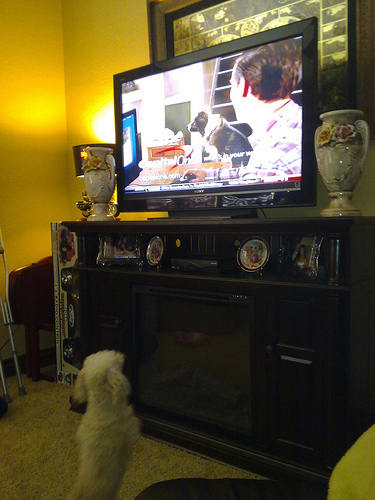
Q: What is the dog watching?
A: Television.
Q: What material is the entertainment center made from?
A: Wood.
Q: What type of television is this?
A: Flat screen.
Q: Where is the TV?
A: Entertainment center.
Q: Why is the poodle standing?
A: Watching TV.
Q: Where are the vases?
A: On the mantle.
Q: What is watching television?
A: A dog.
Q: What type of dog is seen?
A: A poodle.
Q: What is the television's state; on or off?
A: On.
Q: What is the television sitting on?
A: Entertainment center.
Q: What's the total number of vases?
A: 2.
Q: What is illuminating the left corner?
A: A lamp.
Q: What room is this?
A: Living room.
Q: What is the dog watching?
A: TV.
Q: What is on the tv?
A: Commercial.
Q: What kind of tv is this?
A: Flat screen.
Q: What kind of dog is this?
A: Poodle.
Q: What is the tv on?
A: Wooden stand.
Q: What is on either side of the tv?
A: Vases.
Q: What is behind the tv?
A: Picture.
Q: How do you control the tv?
A: Remote control.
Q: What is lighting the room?
A: Lamp.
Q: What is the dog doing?
A: Watching tv.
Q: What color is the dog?
A: White.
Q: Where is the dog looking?
A: At the tv.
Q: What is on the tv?
A: A man and a dog.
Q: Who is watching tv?
A: The dog.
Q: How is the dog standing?
A: On its back legs.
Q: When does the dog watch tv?
A: When the tv is on.